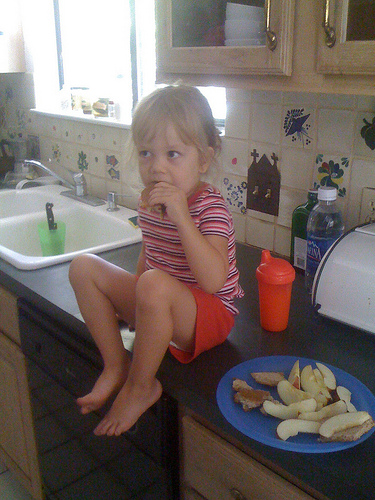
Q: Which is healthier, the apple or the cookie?
A: The apple is healthier than the cookie.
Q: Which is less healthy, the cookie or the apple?
A: The cookie is less healthy than the apple.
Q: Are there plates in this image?
A: Yes, there is a plate.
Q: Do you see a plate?
A: Yes, there is a plate.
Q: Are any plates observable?
A: Yes, there is a plate.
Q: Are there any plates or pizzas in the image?
A: Yes, there is a plate.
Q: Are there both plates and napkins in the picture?
A: No, there is a plate but no napkins.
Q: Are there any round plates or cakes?
A: Yes, there is a round plate.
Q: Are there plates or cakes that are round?
A: Yes, the plate is round.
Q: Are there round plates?
A: Yes, there is a round plate.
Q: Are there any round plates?
A: Yes, there is a round plate.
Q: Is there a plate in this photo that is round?
A: Yes, there is a plate that is round.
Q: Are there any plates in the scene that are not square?
A: Yes, there is a round plate.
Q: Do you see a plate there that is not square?
A: Yes, there is a round plate.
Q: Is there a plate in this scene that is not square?
A: Yes, there is a round plate.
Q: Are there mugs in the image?
A: No, there are no mugs.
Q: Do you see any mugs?
A: No, there are no mugs.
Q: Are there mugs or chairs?
A: No, there are no mugs or chairs.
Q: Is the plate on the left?
A: No, the plate is on the right of the image.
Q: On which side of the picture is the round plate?
A: The plate is on the right of the image.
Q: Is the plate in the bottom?
A: Yes, the plate is in the bottom of the image.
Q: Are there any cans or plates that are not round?
A: No, there is a plate but it is round.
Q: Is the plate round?
A: Yes, the plate is round.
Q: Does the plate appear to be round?
A: Yes, the plate is round.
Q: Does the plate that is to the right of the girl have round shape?
A: Yes, the plate is round.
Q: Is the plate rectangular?
A: No, the plate is round.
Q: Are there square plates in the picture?
A: No, there is a plate but it is round.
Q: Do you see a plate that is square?
A: No, there is a plate but it is round.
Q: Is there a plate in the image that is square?
A: No, there is a plate but it is round.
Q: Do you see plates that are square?
A: No, there is a plate but it is round.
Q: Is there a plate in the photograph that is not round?
A: No, there is a plate but it is round.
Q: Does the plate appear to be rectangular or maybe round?
A: The plate is round.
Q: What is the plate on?
A: The plate is on the counter.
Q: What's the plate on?
A: The plate is on the counter.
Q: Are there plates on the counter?
A: Yes, there is a plate on the counter.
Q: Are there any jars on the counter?
A: No, there is a plate on the counter.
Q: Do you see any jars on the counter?
A: No, there is a plate on the counter.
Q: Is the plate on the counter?
A: Yes, the plate is on the counter.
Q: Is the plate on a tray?
A: No, the plate is on the counter.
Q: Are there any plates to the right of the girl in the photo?
A: Yes, there is a plate to the right of the girl.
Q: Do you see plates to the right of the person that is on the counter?
A: Yes, there is a plate to the right of the girl.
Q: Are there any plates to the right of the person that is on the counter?
A: Yes, there is a plate to the right of the girl.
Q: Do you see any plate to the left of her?
A: No, the plate is to the right of the girl.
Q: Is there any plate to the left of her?
A: No, the plate is to the right of the girl.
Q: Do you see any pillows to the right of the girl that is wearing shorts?
A: No, there is a plate to the right of the girl.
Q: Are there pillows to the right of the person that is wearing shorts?
A: No, there is a plate to the right of the girl.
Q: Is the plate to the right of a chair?
A: No, the plate is to the right of the girl.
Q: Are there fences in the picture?
A: No, there are no fences.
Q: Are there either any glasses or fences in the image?
A: No, there are no fences or glasses.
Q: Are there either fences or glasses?
A: No, there are no fences or glasses.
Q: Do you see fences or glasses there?
A: No, there are no fences or glasses.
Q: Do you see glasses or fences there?
A: No, there are no fences or glasses.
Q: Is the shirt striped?
A: Yes, the shirt is striped.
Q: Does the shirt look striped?
A: Yes, the shirt is striped.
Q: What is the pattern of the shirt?
A: The shirt is striped.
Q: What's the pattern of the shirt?
A: The shirt is striped.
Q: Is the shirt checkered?
A: No, the shirt is striped.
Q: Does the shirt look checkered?
A: No, the shirt is striped.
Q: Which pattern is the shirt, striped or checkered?
A: The shirt is striped.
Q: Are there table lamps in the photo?
A: No, there are no table lamps.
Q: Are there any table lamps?
A: No, there are no table lamps.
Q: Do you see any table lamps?
A: No, there are no table lamps.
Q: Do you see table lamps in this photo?
A: No, there are no table lamps.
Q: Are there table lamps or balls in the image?
A: No, there are no table lamps or balls.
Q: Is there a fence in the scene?
A: No, there are no fences.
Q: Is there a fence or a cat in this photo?
A: No, there are no fences or cats.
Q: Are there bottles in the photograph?
A: Yes, there is a bottle.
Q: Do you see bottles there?
A: Yes, there is a bottle.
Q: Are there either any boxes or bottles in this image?
A: Yes, there is a bottle.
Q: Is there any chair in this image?
A: No, there are no chairs.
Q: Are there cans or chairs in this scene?
A: No, there are no chairs or cans.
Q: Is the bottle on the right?
A: Yes, the bottle is on the right of the image.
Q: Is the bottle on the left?
A: No, the bottle is on the right of the image.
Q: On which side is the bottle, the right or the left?
A: The bottle is on the right of the image.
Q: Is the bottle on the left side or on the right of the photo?
A: The bottle is on the right of the image.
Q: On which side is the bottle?
A: The bottle is on the right of the image.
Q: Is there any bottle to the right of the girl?
A: Yes, there is a bottle to the right of the girl.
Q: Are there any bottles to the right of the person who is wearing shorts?
A: Yes, there is a bottle to the right of the girl.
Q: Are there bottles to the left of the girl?
A: No, the bottle is to the right of the girl.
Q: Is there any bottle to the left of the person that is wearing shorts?
A: No, the bottle is to the right of the girl.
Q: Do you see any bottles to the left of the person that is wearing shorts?
A: No, the bottle is to the right of the girl.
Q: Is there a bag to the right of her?
A: No, there is a bottle to the right of the girl.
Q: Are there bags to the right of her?
A: No, there is a bottle to the right of the girl.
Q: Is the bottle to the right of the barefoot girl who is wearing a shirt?
A: Yes, the bottle is to the right of the girl.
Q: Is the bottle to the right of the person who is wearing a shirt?
A: Yes, the bottle is to the right of the girl.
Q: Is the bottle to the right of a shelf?
A: No, the bottle is to the right of the girl.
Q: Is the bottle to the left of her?
A: No, the bottle is to the right of a girl.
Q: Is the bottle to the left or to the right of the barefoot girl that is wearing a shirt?
A: The bottle is to the right of the girl.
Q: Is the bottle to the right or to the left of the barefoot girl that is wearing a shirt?
A: The bottle is to the right of the girl.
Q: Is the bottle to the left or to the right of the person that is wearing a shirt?
A: The bottle is to the right of the girl.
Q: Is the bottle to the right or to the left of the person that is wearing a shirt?
A: The bottle is to the right of the girl.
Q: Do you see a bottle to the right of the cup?
A: Yes, there is a bottle to the right of the cup.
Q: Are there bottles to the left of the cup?
A: No, the bottle is to the right of the cup.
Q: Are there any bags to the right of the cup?
A: No, there is a bottle to the right of the cup.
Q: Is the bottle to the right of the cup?
A: Yes, the bottle is to the right of the cup.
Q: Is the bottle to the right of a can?
A: No, the bottle is to the right of the cup.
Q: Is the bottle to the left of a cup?
A: No, the bottle is to the right of a cup.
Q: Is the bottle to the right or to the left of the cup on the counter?
A: The bottle is to the right of the cup.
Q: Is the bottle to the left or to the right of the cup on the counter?
A: The bottle is to the right of the cup.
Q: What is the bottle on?
A: The bottle is on the counter.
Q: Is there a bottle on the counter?
A: Yes, there is a bottle on the counter.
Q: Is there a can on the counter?
A: No, there is a bottle on the counter.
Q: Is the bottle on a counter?
A: Yes, the bottle is on a counter.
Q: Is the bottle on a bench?
A: No, the bottle is on a counter.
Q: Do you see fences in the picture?
A: No, there are no fences.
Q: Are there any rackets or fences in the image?
A: No, there are no fences or rackets.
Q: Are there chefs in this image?
A: No, there are no chefs.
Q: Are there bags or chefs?
A: No, there are no chefs or bags.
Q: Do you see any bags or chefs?
A: No, there are no chefs or bags.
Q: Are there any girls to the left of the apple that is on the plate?
A: Yes, there is a girl to the left of the apple.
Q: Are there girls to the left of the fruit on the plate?
A: Yes, there is a girl to the left of the apple.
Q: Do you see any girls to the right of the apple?
A: No, the girl is to the left of the apple.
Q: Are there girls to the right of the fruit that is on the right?
A: No, the girl is to the left of the apple.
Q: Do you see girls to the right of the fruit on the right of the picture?
A: No, the girl is to the left of the apple.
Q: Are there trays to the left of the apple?
A: No, there is a girl to the left of the apple.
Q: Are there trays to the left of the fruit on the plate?
A: No, there is a girl to the left of the apple.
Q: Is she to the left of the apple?
A: Yes, the girl is to the left of the apple.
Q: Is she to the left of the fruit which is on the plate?
A: Yes, the girl is to the left of the apple.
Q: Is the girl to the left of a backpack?
A: No, the girl is to the left of the apple.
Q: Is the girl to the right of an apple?
A: No, the girl is to the left of an apple.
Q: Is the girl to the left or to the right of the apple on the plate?
A: The girl is to the left of the apple.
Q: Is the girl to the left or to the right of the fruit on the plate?
A: The girl is to the left of the apple.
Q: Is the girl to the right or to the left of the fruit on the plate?
A: The girl is to the left of the apple.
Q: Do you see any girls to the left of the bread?
A: Yes, there is a girl to the left of the bread.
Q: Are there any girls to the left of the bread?
A: Yes, there is a girl to the left of the bread.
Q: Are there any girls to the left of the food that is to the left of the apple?
A: Yes, there is a girl to the left of the bread.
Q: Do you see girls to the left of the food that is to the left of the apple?
A: Yes, there is a girl to the left of the bread.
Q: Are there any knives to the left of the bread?
A: No, there is a girl to the left of the bread.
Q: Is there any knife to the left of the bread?
A: No, there is a girl to the left of the bread.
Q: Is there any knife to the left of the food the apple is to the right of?
A: No, there is a girl to the left of the bread.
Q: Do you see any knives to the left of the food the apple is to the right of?
A: No, there is a girl to the left of the bread.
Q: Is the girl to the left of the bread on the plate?
A: Yes, the girl is to the left of the bread.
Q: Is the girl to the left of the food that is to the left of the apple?
A: Yes, the girl is to the left of the bread.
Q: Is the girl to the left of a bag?
A: No, the girl is to the left of the bread.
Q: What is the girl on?
A: The girl is on the counter.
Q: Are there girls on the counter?
A: Yes, there is a girl on the counter.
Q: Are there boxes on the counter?
A: No, there is a girl on the counter.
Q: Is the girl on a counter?
A: Yes, the girl is on a counter.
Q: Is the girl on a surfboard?
A: No, the girl is on a counter.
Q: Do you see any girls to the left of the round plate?
A: Yes, there is a girl to the left of the plate.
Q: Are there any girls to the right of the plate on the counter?
A: No, the girl is to the left of the plate.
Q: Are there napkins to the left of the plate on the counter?
A: No, there is a girl to the left of the plate.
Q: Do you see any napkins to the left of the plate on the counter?
A: No, there is a girl to the left of the plate.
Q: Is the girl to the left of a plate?
A: Yes, the girl is to the left of a plate.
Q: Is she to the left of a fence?
A: No, the girl is to the left of a plate.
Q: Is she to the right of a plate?
A: No, the girl is to the left of a plate.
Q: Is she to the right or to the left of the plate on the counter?
A: The girl is to the left of the plate.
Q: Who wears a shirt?
A: The girl wears a shirt.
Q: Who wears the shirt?
A: The girl wears a shirt.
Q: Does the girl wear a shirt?
A: Yes, the girl wears a shirt.